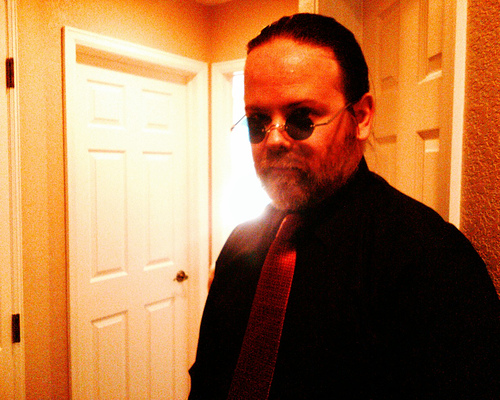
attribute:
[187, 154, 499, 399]
shirt — black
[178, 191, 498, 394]
shirt — black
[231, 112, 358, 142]
sunglasses — small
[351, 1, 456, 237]
door — closed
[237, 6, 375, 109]
hair — black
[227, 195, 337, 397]
tie — red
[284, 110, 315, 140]
lenses — round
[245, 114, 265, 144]
lenses — round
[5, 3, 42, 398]
trim — white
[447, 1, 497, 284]
wall — textured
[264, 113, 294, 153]
nose — short, stubby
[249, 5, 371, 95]
hair — black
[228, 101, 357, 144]
sunglasses — black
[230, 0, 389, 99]
hair — pulled back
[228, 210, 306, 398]
necktie — red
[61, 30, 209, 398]
door — white, closed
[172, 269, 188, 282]
handle — brass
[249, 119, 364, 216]
beard — grey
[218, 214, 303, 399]
tie — red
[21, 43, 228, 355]
door — white